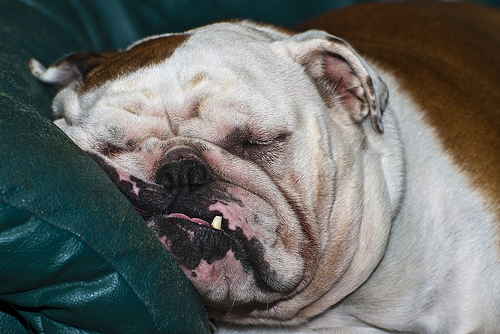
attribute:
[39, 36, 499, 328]
nose — bull dog, black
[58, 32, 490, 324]
dog — bull, sleeping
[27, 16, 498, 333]
bull dog — resting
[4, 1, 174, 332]
cushion — green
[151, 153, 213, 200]
nose — black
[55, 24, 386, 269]
wall decoration — sleeping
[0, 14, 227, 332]
cushion — white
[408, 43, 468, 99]
fur — brown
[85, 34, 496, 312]
dog — white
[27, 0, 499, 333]
dog — brown, bull, laying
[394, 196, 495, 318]
fur — white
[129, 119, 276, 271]
nose — black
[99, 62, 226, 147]
furrow — wrinkled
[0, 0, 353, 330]
cushion — sofa, green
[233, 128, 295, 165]
eye — closed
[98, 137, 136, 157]
eye — closed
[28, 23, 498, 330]
bulldog — brown, pink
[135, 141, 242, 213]
nose — black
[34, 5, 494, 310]
bull dog — white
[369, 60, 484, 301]
fur — white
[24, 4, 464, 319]
dog — brown